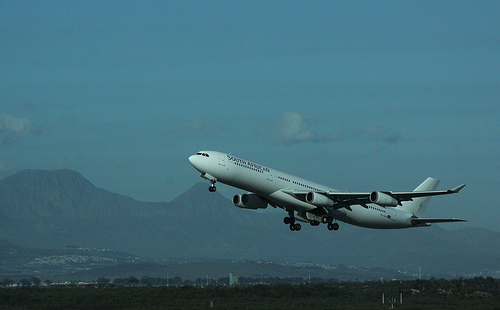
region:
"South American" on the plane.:
[210, 150, 277, 177]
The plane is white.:
[170, 135, 470, 262]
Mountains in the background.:
[10, 162, 495, 282]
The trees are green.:
[125, 285, 461, 305]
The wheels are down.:
[272, 211, 343, 229]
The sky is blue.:
[79, 23, 215, 85]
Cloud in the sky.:
[268, 102, 357, 148]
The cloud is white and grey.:
[275, 110, 322, 150]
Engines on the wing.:
[298, 182, 400, 212]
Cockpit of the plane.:
[182, 144, 224, 181]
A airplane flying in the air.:
[166, 130, 469, 243]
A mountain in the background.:
[4, 151, 199, 257]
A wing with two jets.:
[292, 182, 462, 209]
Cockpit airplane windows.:
[195, 149, 215, 162]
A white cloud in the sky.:
[250, 99, 381, 158]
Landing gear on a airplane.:
[280, 211, 341, 237]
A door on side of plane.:
[216, 152, 228, 166]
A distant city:
[231, 250, 445, 285]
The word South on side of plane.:
[222, 154, 243, 164]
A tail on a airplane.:
[395, 167, 459, 227]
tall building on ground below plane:
[224, 268, 241, 289]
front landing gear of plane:
[204, 182, 220, 195]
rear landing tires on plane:
[281, 211, 342, 237]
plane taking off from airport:
[166, 127, 469, 257]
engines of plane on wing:
[294, 187, 472, 214]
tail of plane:
[395, 172, 443, 219]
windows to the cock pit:
[191, 148, 213, 160]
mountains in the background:
[7, 156, 162, 245]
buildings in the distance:
[28, 252, 105, 272]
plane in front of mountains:
[154, 130, 494, 268]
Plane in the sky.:
[175, 142, 480, 242]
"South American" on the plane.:
[218, 151, 284, 182]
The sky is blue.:
[67, 37, 204, 117]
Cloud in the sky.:
[270, 112, 397, 164]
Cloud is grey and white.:
[276, 110, 336, 145]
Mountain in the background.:
[14, 166, 206, 242]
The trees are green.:
[216, 285, 409, 309]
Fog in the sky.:
[23, 137, 208, 257]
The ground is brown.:
[141, 257, 341, 279]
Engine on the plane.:
[303, 187, 422, 211]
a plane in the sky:
[184, 142, 474, 240]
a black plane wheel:
[203, 180, 220, 194]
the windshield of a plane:
[191, 148, 213, 158]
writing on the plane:
[218, 152, 274, 175]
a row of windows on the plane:
[274, 172, 329, 194]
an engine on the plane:
[301, 188, 341, 208]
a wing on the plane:
[279, 180, 469, 203]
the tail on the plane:
[393, 169, 453, 219]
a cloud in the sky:
[263, 101, 411, 158]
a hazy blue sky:
[0, 0, 499, 227]